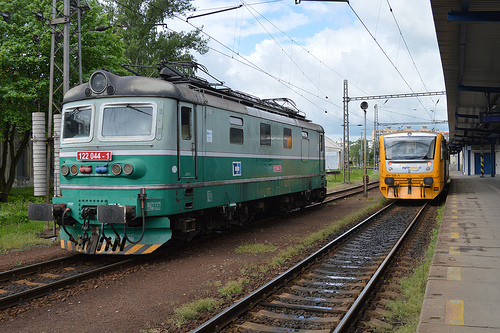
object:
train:
[373, 126, 452, 204]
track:
[184, 202, 432, 333]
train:
[48, 70, 329, 254]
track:
[0, 188, 376, 303]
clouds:
[312, 28, 365, 53]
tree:
[1, 1, 31, 204]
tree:
[106, 0, 161, 71]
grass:
[0, 202, 22, 245]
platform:
[410, 173, 500, 333]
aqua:
[147, 163, 159, 176]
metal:
[180, 202, 429, 333]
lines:
[444, 178, 465, 333]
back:
[480, 109, 500, 124]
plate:
[75, 150, 114, 164]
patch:
[231, 238, 275, 255]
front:
[383, 132, 438, 163]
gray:
[60, 62, 324, 133]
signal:
[357, 101, 371, 198]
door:
[177, 100, 198, 186]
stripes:
[56, 238, 161, 257]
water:
[329, 275, 359, 283]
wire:
[343, 2, 441, 129]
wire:
[378, 0, 436, 107]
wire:
[236, 0, 378, 128]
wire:
[192, 41, 376, 128]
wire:
[237, 0, 394, 109]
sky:
[232, 33, 262, 52]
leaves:
[3, 83, 38, 104]